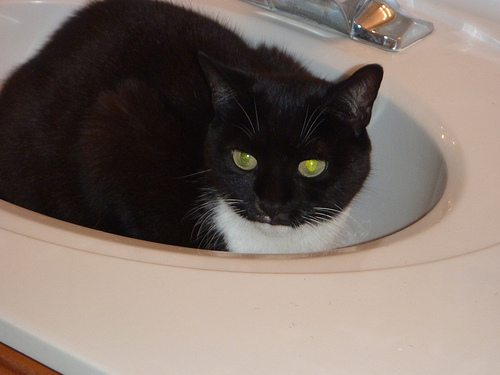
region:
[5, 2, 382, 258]
black and white cat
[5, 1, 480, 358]
cat sitting in a sink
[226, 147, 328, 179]
bright green cat eyes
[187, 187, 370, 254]
short thick white whiskers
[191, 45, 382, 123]
small pointy ears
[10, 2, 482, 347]
white porcelain sink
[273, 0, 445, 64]
chrome sick faucet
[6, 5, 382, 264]
cat sitting curled up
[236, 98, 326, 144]
long whiskers above the cats eyes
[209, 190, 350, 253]
white patch on the cats chest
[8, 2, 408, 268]
Black and white cat in a sink.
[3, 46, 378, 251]
black cat with green eyes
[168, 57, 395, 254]
green eyed cat in sink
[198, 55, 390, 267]
Black cat with white neck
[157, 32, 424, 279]
medium sized kitty cat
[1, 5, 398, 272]
One cat sitting in a sink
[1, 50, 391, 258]
mostly black cat with white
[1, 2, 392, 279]
green eyed cat in sink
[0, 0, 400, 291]
Medium sized black cat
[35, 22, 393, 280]
medium sized cat in sink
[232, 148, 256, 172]
the green eye of a cat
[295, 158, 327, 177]
the green eye of a cat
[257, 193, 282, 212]
the nose of the cat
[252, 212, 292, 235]
the black and white cat mouth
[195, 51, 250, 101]
the black ear of the cat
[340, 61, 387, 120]
the black ear of the cat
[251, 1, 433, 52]
the bottom of the silver faucet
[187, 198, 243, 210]
the long white whisker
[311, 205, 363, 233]
the long white whisker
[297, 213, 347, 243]
the long white whisker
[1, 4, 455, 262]
a cat laying in a bathroom sink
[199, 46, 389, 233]
the head of a cat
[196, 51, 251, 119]
the ear of a cat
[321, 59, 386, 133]
the ear of a cat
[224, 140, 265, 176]
the eye of a cat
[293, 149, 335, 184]
the eye of a cat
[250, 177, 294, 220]
the nose of a cat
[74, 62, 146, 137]
the fur of a cat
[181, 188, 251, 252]
the whiskers of a cat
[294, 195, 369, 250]
the whiskers of a cat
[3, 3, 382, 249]
a black cat in bathroom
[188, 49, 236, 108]
right ear on the cat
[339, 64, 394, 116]
left ear on the cat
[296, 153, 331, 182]
left eye on the cat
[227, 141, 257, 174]
right eye on cat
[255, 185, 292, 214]
nose on the black cat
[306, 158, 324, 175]
left green eyeball on cat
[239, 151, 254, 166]
right green eyeball on cat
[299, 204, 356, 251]
whiskers on left side of face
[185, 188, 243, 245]
whiskers on right side of cat's face